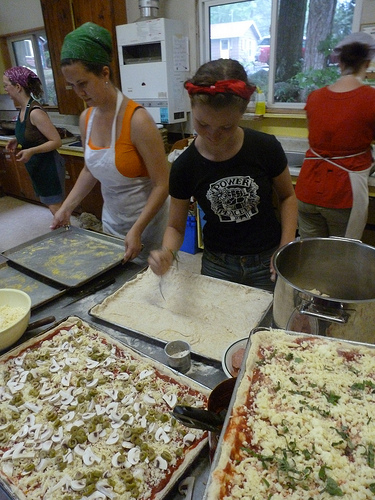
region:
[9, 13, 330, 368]
The women are making pizza.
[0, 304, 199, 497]
Mushrooms and olives are on the pizza.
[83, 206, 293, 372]
The girl pokes the pizza dough with a fork.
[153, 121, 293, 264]
The girl wears a black t-shirt.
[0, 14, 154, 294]
The woman prepares the pizza tray.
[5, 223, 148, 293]
Cornmeal is on the pizza tray.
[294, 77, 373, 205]
The woman wears a red top.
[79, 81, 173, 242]
The woman wears a white apron.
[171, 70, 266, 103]
The girl wears a red headband.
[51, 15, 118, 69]
The woman wears a green scarf.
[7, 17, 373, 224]
a group of girls in a kitchen with scarves on their heads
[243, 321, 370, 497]
a raw pizza ready to be baked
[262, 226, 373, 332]
a very large stainless steel pot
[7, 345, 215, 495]
a large raw pizza with mushrooms on it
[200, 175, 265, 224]
he white design on a girl's black t-shirt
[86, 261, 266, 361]
raw pizza dough pressed into a pan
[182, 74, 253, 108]
a red scarf tied on a girl's head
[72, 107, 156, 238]
a white apron the girl is wearing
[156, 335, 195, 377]
a cup holding flour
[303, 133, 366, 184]
crossed white apron strings on a girl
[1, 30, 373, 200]
four woman in the kitchen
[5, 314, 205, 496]
a large square pizza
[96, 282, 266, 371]
a uncooked pizza crust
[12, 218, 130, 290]
a dirty pizza pan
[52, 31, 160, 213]
a girl wearing a white apron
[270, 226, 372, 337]
a big silver pot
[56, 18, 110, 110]
a girl wearing a green bandana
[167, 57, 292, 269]
a young lady in a black shirt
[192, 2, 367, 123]
view of trees out the window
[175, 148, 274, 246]
black shirt that says power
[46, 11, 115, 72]
a dark green bandana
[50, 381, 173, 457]
mushroom and olive toppings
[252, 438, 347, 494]
shredded basil on cheese pizza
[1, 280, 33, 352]
A white bowl full of cheese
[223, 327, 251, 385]
blue and white bowl of pepperoni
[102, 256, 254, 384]
a plain rectangular pizza crust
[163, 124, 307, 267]
a girl's black and white t-shirt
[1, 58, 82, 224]
a woman in glasses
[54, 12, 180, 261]
a dark haired girl in orange and white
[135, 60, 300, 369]
Woman flattening dough for pizzas.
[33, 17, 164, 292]
Woman with dirty tray.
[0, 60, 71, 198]
Woman in purple scarf standing in kitchen.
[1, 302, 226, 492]
Rectangular pizza ready to bake.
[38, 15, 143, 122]
Woman in green scarf holding dirty tray.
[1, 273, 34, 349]
Bowl of cheese for the pizzas.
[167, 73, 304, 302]
Woman in black shirt making dough.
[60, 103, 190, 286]
Woman in apron holding pan.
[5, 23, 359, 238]
Four women in a kitchen making pizzas.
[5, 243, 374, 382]
Women making homemade pizzas.